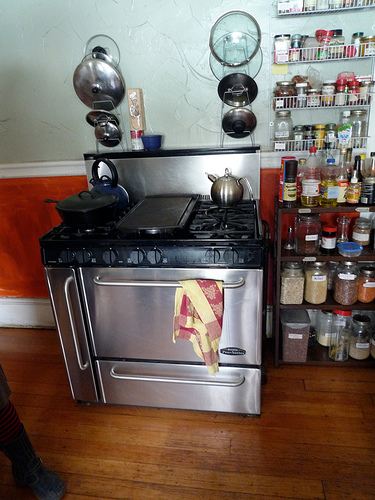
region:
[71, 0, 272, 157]
racks with pot and pan lids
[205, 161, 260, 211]
round metal tea kettle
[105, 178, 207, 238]
black stove top griddle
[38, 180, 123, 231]
black cast iron pan with lid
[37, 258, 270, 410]
stainless steel oven door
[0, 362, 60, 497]
leg with stripped stocking and black boot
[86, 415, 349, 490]
hardwood floor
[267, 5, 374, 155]
wall mounted spice rack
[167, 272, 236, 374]
yellow and red tea towel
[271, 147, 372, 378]
shelf with cooking ingredients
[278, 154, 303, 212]
glass bottle filled with spices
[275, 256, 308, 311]
glass jar filled with cooking products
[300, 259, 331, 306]
glass jar filled with cooking products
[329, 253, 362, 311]
glass jar filled with cooking products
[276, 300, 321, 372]
glass jar filled with cooking products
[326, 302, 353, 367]
glass jar filled with cooking products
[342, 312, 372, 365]
glass jar filled with cooking products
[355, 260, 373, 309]
glass jar filled with cooking products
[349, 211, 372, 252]
glass jar filled with cooking products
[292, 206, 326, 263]
glass jar filled with cooking products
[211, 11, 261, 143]
A set of covers for pans.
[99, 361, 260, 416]
The bottom portion of the oven.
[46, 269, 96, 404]
The left portion of the oven.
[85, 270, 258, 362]
The top portion of the oven.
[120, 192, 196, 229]
The main heating plate of the oven.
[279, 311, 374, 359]
A set of grain-based ingredients.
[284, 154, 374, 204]
A set of cooking oils.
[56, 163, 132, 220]
A black pan and a blue cooking pot.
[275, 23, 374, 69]
A group of peppers and salts.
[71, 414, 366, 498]
The wooden tiled floor of the area.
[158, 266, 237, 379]
red and yellow checkered dishcloth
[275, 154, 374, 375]
multiple spices on shelves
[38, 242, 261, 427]
stainless steel stovefront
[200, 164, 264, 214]
shiny tea kettle on stovetop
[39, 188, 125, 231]
dark matte frying pan with lid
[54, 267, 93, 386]
vertical stainless steel oven handle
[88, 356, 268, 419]
stainless steel bottom oven door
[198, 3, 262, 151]
pot lids on wall rack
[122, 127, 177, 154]
little blue bowl next to Campbell's soup can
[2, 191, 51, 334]
white baseboard against orange wall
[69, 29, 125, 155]
rack holding pot lids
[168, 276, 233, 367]
yellow and red kitchen towel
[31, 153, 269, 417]
stainless steel gas stove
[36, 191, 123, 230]
cast iron skillet with cover on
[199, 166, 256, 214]
stainless steel whistling tea kettle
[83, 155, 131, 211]
blue whistling tea kettle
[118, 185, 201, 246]
griddle pan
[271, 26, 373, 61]
jars of spices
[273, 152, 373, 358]
storage shelves with labeled cooking supplies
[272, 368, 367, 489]
wood plank floors